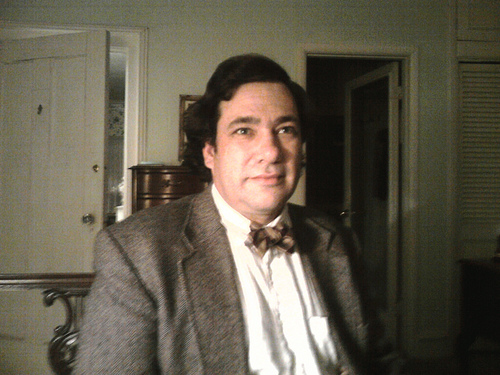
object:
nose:
[253, 123, 283, 165]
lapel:
[293, 217, 351, 350]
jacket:
[69, 182, 408, 375]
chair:
[0, 267, 96, 375]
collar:
[210, 184, 295, 258]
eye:
[233, 127, 252, 134]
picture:
[178, 93, 253, 161]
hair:
[183, 53, 314, 183]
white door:
[0, 27, 108, 375]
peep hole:
[35, 103, 43, 115]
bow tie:
[243, 220, 298, 259]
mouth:
[246, 172, 285, 187]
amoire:
[127, 163, 204, 214]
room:
[2, 0, 496, 372]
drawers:
[128, 163, 204, 213]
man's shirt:
[205, 182, 347, 374]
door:
[0, 22, 148, 374]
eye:
[276, 125, 298, 136]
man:
[67, 54, 407, 375]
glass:
[350, 77, 389, 317]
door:
[333, 60, 399, 357]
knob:
[81, 213, 94, 225]